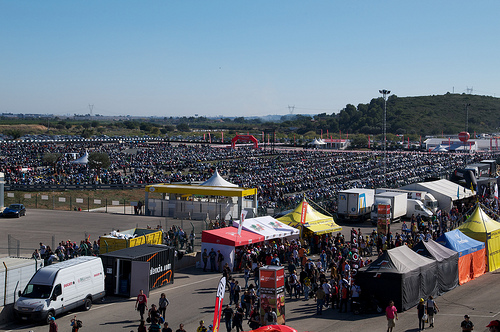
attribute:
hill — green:
[273, 96, 498, 134]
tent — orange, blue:
[436, 226, 486, 285]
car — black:
[2, 200, 25, 218]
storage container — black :
[99, 242, 174, 297]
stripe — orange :
[145, 248, 157, 265]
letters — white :
[149, 260, 171, 275]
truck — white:
[336, 186, 376, 225]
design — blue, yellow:
[356, 192, 366, 214]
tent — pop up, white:
[409, 172, 465, 227]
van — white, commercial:
[11, 252, 107, 322]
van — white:
[19, 214, 124, 317]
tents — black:
[356, 242, 438, 314]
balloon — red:
[456, 127, 471, 144]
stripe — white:
[454, 130, 471, 138]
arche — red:
[234, 137, 256, 147]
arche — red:
[231, 132, 262, 148]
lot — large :
[2, 139, 499, 224]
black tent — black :
[419, 235, 461, 292]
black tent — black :
[367, 245, 436, 307]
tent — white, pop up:
[229, 210, 304, 267]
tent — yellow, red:
[361, 240, 465, 308]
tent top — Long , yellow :
[291, 197, 341, 233]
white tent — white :
[233, 215, 298, 242]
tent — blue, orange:
[441, 226, 486, 285]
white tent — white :
[242, 207, 301, 250]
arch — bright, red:
[223, 130, 265, 151]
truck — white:
[9, 251, 106, 328]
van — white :
[17, 242, 127, 311]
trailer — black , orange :
[100, 240, 175, 298]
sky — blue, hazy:
[0, 0, 497, 102]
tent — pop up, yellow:
[457, 203, 498, 273]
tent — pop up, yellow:
[276, 195, 335, 252]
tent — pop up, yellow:
[357, 242, 437, 311]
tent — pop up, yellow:
[437, 227, 487, 282]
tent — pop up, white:
[204, 165, 238, 192]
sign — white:
[72, 198, 85, 204]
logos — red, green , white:
[246, 210, 296, 240]